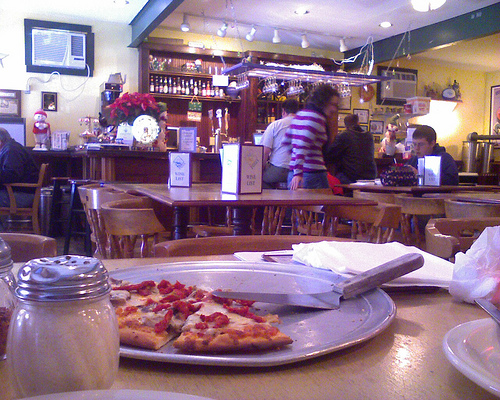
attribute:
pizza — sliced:
[110, 266, 290, 364]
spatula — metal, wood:
[203, 243, 434, 312]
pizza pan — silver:
[105, 255, 397, 368]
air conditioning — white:
[25, 20, 94, 75]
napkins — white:
[290, 233, 464, 289]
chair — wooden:
[98, 187, 166, 252]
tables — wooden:
[150, 164, 493, 209]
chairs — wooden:
[62, 176, 179, 261]